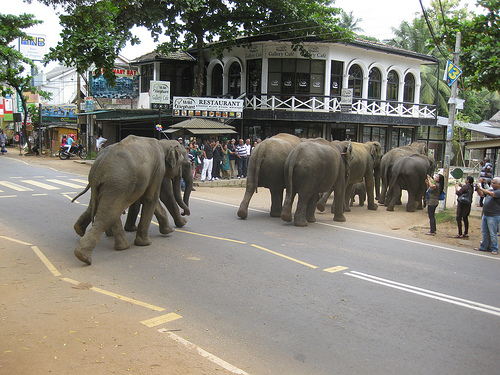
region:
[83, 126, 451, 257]
many elephants in the photo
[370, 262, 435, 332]
lines on the street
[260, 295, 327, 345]
black street under elephant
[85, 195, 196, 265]
legs of the elephant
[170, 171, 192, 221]
trunk of the elephant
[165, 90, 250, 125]
sign on the building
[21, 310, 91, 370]
dirt on the ground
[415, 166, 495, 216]
people next to the elephants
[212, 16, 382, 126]
building next to the elephants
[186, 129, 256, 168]
people next to the elephants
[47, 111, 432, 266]
Elephants in the foreground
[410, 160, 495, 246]
People taking photos of elephants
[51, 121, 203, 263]
Elephants in the street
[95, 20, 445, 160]
A building in the background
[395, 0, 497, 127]
A tall tree in the background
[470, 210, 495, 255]
Person is wearing blue jeans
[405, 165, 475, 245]
Two women in the background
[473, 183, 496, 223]
Man is wearing a gray shirt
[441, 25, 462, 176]
A wooden pole in the background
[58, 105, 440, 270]
Elephants are gray in color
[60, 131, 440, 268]
group of elephants crossing the street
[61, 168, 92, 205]
grey elephant tail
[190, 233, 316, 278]
yellow line drawn on ground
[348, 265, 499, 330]
double white lines drawn on street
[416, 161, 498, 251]
group of people holding cell phone up and taking photo's of passing elephants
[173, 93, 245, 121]
restaurant sign on elevated awning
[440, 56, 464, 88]
blue and yellow poster hanging on metal pole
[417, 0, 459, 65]
black power lines in sky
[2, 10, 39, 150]
green leaf tree with brown trunk on sidewalk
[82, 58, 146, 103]
red and blue store sign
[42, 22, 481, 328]
elephants crossing the street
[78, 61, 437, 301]
elephants crossing the road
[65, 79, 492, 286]
large elephants crossing the road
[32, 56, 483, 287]
large elephants crossing the street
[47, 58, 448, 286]
group of elephants crossing the road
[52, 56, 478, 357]
group of elephants crossing the street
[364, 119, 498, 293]
people taking pictures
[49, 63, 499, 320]
poeple taking pictures of the elephants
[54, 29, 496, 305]
people taking pictures of large elephants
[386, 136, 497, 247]
people standing on the sidewalk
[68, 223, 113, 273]
Rear right foot of an elphant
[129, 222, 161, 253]
Front right foot of an elphant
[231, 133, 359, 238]
Two elephants crossing a road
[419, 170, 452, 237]
Woman taking a picture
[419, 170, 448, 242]
Woman watching a group of elephants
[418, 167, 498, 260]
Three people taking pictures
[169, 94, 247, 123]
Restaurant sign on building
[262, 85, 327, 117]
Black and white railing on building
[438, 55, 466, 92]
Blue and yellow sign on pole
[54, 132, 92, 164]
Person riding motorcycle near building